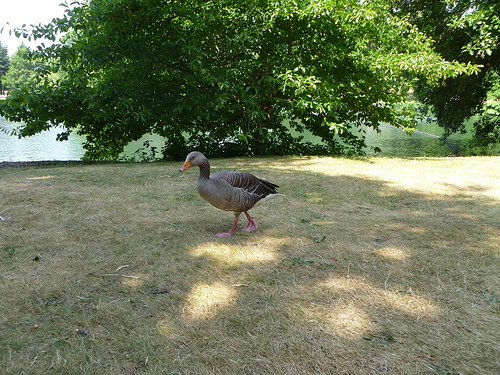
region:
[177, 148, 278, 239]
a single duck walking forward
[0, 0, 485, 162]
a large, leafy tree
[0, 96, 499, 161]
a river with sunlight reflecting off its surface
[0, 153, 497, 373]
an expanse of yellowed grass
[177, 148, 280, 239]
a grey duck with white underside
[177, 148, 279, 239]
a small duck with orange beak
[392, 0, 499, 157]
a bushy green tree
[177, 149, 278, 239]
A duck with reddish colored feet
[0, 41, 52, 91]
a tree visible in the distance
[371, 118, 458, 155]
a long gray stick in the water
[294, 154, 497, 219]
sunshine shows on the ground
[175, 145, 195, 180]
a goose's orange beak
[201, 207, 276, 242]
the legs are orange and feet webbed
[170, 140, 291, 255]
brown goose walks alone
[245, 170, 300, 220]
white feathers peek out in rear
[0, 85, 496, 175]
water is behind the large bush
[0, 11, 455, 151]
a very large bush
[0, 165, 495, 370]
grass is dry and faded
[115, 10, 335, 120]
leaves are green on the bush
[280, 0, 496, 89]
large area of sunshine on the bush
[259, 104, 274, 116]
leaves on the tree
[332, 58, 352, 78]
leaves on the tree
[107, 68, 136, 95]
leaves on the tree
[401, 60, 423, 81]
leaves on the tree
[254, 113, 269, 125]
leaves on the tree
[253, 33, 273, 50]
leaves on the tree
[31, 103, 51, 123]
leaves on the tree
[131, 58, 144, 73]
leaves on the tree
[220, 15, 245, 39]
leaves on the tree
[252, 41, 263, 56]
leaves on the tree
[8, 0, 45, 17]
white clouds in blue sky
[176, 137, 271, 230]
gray goose walking on grass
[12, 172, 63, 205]
short green and yellow grass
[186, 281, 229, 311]
short green and yellow grass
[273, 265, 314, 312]
short green and yellow grass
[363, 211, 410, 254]
short green and yellow grass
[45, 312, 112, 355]
short green and yellow grass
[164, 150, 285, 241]
gray goose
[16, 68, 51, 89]
green leaves in brown tree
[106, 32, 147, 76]
green leaves in brown tree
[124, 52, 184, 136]
green leaves in brown tree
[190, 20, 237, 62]
green leaves in brown tree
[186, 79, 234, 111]
green leaves in brown tree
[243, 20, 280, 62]
green leaves in brown tree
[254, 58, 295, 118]
green leaves in brown tree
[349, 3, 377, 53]
green leaves in brown tree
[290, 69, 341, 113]
green leaves in brown tree